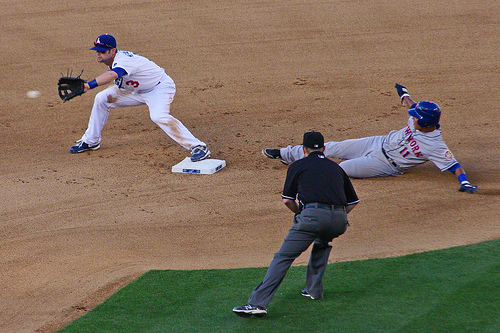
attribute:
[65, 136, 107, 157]
cleats — blue, white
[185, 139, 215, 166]
cleats — blue, white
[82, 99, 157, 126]
hat — blue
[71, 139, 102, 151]
shoe — blue 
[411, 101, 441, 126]
helmet — blue 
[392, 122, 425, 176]
number — blue, orange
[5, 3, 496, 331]
scene — outdoor scene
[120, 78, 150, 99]
number — red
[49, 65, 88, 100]
glove — black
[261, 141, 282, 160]
shoes — black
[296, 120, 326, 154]
hat — black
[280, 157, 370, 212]
shirt — black